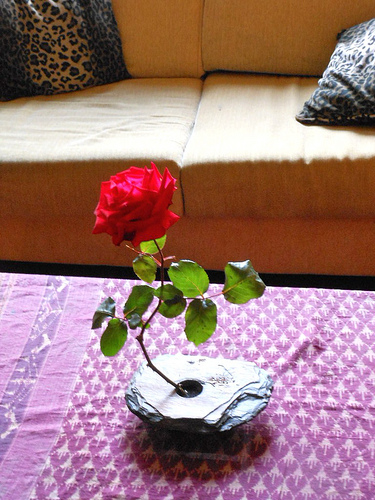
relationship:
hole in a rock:
[178, 378, 201, 396] [125, 356, 273, 431]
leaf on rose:
[91, 281, 155, 354] [82, 171, 264, 420]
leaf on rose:
[158, 254, 265, 345] [82, 171, 264, 420]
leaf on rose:
[117, 229, 166, 285] [82, 171, 264, 420]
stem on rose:
[136, 236, 186, 394] [92, 167, 263, 397]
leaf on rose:
[222, 258, 265, 306] [70, 129, 198, 302]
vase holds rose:
[114, 355, 279, 440] [83, 157, 274, 407]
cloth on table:
[1, 272, 373, 498] [2, 269, 370, 498]